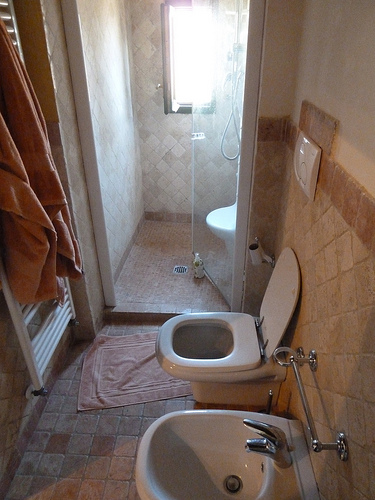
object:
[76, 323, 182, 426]
towel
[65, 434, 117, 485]
floor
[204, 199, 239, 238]
bidet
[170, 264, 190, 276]
drain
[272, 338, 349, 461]
metal bar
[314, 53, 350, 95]
wall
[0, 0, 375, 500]
toilet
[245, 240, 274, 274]
toilet paper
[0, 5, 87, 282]
other towel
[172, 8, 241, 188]
shower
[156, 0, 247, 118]
window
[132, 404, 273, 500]
sink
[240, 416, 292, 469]
faucet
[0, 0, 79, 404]
towel rack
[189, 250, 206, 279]
bottle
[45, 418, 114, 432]
tiles